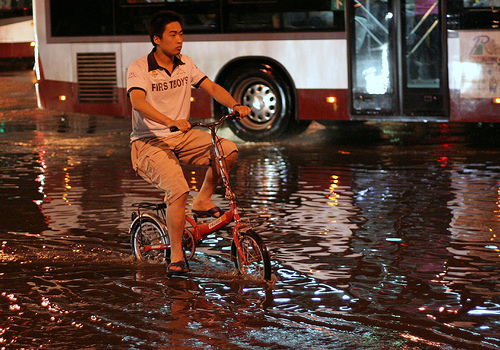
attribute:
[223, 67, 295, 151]
tire — black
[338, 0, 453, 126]
doors — double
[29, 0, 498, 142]
bus — red and white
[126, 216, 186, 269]
tire — black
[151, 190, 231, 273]
flip flops — black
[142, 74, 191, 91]
lettering — black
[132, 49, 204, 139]
shirt — white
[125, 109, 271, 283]
bicycle — red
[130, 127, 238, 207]
shorts — khaki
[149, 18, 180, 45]
hair — black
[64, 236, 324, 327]
street — flooded 